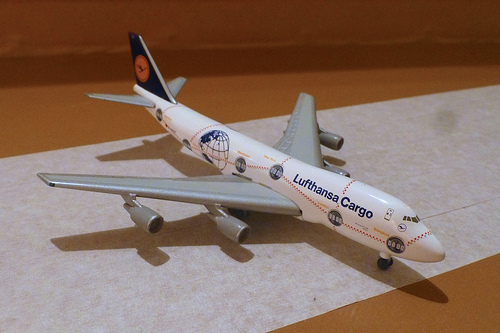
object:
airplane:
[36, 31, 446, 270]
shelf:
[2, 63, 496, 326]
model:
[36, 32, 448, 272]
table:
[0, 0, 499, 333]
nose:
[419, 242, 446, 264]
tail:
[127, 29, 180, 105]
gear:
[376, 257, 393, 271]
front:
[339, 189, 446, 270]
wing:
[35, 173, 302, 218]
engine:
[123, 201, 165, 233]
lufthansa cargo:
[290, 174, 373, 218]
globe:
[198, 130, 230, 171]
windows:
[403, 216, 411, 222]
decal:
[132, 55, 150, 83]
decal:
[384, 208, 394, 221]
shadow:
[50, 212, 450, 305]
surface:
[0, 0, 499, 332]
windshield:
[411, 215, 420, 223]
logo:
[266, 163, 284, 180]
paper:
[47, 253, 319, 325]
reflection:
[176, 39, 457, 117]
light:
[223, 83, 500, 125]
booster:
[317, 129, 343, 151]